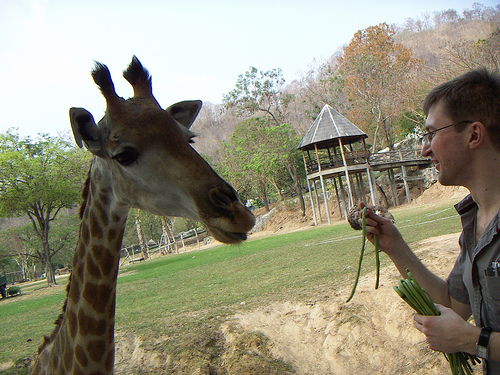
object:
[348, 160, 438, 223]
ground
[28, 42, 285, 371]
giraffe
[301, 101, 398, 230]
platform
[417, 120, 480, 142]
glasses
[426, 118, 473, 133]
frame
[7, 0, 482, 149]
sky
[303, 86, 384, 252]
observation area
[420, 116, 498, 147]
eye glasses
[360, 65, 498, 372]
man's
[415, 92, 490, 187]
face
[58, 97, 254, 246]
face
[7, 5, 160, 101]
white clouds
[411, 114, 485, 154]
glasses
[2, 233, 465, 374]
grass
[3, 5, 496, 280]
background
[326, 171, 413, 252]
bird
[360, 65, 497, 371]
man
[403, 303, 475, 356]
hand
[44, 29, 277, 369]
giraffe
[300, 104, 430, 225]
gazebo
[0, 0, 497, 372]
zoo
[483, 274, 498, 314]
pocket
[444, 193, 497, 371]
shirt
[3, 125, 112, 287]
tree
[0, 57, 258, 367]
giraffe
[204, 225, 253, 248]
beard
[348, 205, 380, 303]
celery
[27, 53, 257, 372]
giraffe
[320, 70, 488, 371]
man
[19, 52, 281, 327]
giraffe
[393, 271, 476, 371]
food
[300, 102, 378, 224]
gazebo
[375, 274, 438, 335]
plants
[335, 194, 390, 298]
plants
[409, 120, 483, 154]
glasses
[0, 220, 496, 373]
grass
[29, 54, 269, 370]
neck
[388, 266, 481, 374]
celery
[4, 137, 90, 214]
tree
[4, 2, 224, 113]
clouds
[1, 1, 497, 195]
sky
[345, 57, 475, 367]
man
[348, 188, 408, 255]
hand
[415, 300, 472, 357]
left hand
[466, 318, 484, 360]
watch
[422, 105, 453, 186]
face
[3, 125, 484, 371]
habitat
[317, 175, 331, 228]
stilt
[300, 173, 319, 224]
stilt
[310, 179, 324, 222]
stilt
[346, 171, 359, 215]
stilt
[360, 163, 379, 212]
stilt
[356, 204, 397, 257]
hand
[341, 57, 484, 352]
man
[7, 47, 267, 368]
giraffe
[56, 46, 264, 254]
head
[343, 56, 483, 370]
man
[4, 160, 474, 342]
ground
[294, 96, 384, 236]
platform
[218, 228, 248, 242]
tongue